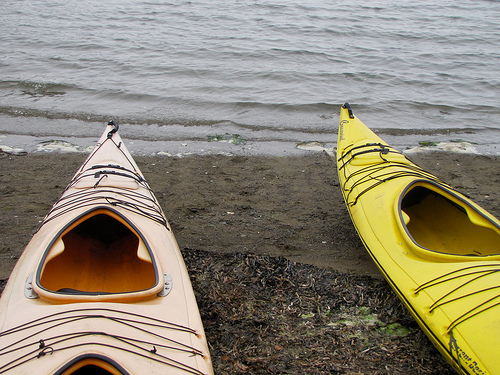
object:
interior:
[39, 210, 154, 293]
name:
[338, 119, 350, 141]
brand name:
[448, 339, 485, 375]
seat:
[56, 286, 117, 296]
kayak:
[333, 128, 494, 333]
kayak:
[3, 100, 235, 372]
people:
[33, 201, 165, 304]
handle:
[107, 119, 119, 137]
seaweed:
[193, 245, 456, 368]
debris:
[219, 242, 339, 371]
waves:
[192, 33, 434, 84]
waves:
[5, 90, 296, 137]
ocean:
[1, 1, 484, 162]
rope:
[413, 263, 500, 335]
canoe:
[0, 120, 212, 372]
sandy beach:
[3, 98, 481, 370]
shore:
[1, 144, 484, 373]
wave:
[1, 127, 334, 143]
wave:
[1, 103, 484, 134]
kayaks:
[4, 117, 217, 373]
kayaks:
[334, 100, 497, 369]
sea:
[5, 5, 497, 169]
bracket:
[30, 205, 164, 304]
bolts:
[21, 275, 42, 304]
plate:
[154, 270, 172, 299]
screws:
[157, 268, 171, 295]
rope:
[0, 303, 209, 373]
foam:
[27, 132, 67, 153]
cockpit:
[395, 179, 500, 264]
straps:
[37, 183, 167, 228]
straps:
[337, 141, 472, 206]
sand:
[1, 146, 497, 368]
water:
[6, 3, 496, 165]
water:
[154, 34, 368, 117]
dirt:
[213, 187, 339, 253]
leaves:
[257, 277, 414, 349]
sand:
[200, 192, 350, 367]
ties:
[46, 160, 187, 231]